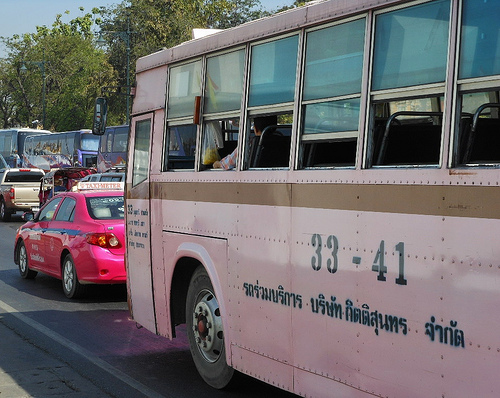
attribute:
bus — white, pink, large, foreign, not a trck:
[124, 0, 498, 395]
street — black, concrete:
[4, 200, 280, 397]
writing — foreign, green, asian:
[238, 230, 467, 356]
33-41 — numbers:
[305, 231, 412, 284]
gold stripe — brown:
[124, 178, 499, 225]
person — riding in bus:
[215, 112, 277, 173]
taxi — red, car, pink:
[15, 182, 129, 300]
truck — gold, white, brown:
[3, 168, 40, 219]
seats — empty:
[308, 105, 500, 163]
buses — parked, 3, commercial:
[1, 126, 132, 175]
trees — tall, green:
[2, 4, 304, 134]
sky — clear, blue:
[1, 1, 313, 56]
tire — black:
[181, 260, 242, 387]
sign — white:
[77, 180, 125, 191]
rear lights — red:
[87, 231, 118, 250]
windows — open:
[168, 1, 499, 168]